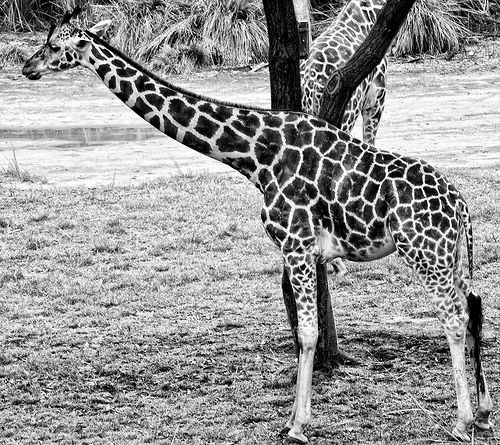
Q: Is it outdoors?
A: Yes, it is outdoors.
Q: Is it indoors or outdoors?
A: It is outdoors.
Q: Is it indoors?
A: No, it is outdoors.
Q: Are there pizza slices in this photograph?
A: No, there are no pizza slices.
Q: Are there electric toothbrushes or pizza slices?
A: No, there are no pizza slices or electric toothbrushes.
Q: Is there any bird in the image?
A: No, there are no birds.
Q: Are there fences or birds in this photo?
A: No, there are no birds or fences.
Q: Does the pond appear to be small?
A: Yes, the pond is small.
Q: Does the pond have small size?
A: Yes, the pond is small.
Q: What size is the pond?
A: The pond is small.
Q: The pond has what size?
A: The pond is small.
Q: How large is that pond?
A: The pond is small.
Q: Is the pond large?
A: No, the pond is small.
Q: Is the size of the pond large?
A: No, the pond is small.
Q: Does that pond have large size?
A: No, the pond is small.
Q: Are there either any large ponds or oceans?
A: No, there is a pond but it is small.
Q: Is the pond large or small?
A: The pond is small.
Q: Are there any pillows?
A: No, there are no pillows.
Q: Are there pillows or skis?
A: No, there are no pillows or skis.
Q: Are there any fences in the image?
A: No, there are no fences.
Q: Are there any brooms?
A: No, there are no brooms.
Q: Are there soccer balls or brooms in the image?
A: No, there are no brooms or soccer balls.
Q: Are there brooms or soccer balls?
A: No, there are no brooms or soccer balls.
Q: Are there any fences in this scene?
A: No, there are no fences.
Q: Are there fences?
A: No, there are no fences.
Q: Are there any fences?
A: No, there are no fences.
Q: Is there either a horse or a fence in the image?
A: No, there are no fences or horses.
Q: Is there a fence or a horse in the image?
A: No, there are no fences or horses.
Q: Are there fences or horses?
A: No, there are no fences or horses.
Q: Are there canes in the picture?
A: No, there are no canes.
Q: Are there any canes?
A: No, there are no canes.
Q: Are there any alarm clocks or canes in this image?
A: No, there are no canes or alarm clocks.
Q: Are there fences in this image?
A: No, there are no fences.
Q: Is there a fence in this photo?
A: No, there are no fences.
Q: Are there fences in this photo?
A: No, there are no fences.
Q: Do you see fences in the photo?
A: No, there are no fences.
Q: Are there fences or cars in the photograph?
A: No, there are no fences or cars.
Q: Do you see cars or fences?
A: No, there are no fences or cars.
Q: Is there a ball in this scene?
A: No, there are no balls.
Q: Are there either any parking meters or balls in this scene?
A: No, there are no balls or parking meters.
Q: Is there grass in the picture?
A: Yes, there is grass.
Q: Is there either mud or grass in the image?
A: Yes, there is grass.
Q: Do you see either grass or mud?
A: Yes, there is grass.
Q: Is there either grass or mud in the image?
A: Yes, there is grass.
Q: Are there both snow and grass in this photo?
A: No, there is grass but no snow.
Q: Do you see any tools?
A: No, there are no tools.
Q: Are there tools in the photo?
A: No, there are no tools.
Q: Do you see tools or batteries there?
A: No, there are no tools or batteries.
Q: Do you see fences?
A: No, there are no fences.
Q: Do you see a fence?
A: No, there are no fences.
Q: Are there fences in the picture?
A: No, there are no fences.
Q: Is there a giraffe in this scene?
A: Yes, there is a giraffe.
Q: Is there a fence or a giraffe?
A: Yes, there is a giraffe.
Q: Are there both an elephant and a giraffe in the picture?
A: No, there is a giraffe but no elephants.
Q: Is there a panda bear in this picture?
A: No, there are no panda bears.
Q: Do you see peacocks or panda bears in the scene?
A: No, there are no panda bears or peacocks.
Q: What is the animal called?
A: The animal is a giraffe.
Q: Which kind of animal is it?
A: The animal is a giraffe.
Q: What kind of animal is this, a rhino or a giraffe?
A: That is a giraffe.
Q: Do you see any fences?
A: No, there are no fences.